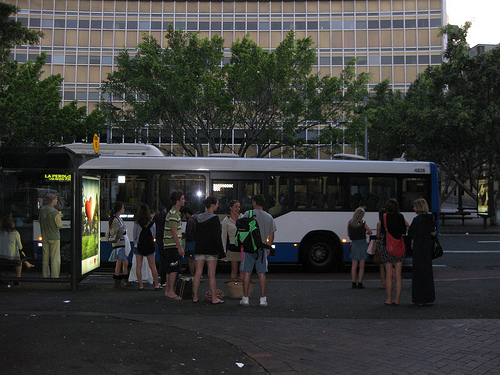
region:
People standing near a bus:
[7, 188, 442, 315]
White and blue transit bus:
[80, 152, 442, 269]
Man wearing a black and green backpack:
[235, 190, 279, 308]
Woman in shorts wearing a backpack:
[127, 199, 162, 291]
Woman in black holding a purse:
[410, 193, 442, 308]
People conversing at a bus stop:
[157, 185, 277, 311]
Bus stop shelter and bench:
[0, 141, 103, 292]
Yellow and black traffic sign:
[87, 131, 101, 154]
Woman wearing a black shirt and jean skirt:
[345, 204, 372, 294]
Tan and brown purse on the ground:
[222, 263, 258, 303]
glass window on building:
[16, 17, 28, 27]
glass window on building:
[53, 18, 64, 29]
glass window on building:
[100, 21, 114, 29]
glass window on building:
[151, 20, 162, 30]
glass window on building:
[198, 20, 210, 32]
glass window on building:
[235, 19, 246, 32]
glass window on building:
[282, 21, 292, 31]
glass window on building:
[307, 19, 319, 29]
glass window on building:
[330, 19, 342, 30]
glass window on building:
[342, 17, 355, 29]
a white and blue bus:
[78, 151, 441, 273]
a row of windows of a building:
[27, 6, 442, 31]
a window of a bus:
[285, 173, 321, 215]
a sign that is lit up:
[75, 170, 102, 288]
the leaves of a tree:
[437, 82, 492, 137]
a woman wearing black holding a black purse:
[405, 195, 445, 307]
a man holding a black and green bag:
[233, 193, 278, 306]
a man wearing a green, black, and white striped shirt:
[160, 188, 187, 303]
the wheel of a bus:
[298, 230, 344, 275]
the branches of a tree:
[175, 117, 287, 155]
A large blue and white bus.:
[46, 137, 464, 290]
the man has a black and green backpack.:
[234, 211, 263, 258]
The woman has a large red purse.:
[379, 211, 404, 262]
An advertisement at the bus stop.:
[73, 167, 107, 297]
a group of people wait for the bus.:
[156, 184, 284, 318]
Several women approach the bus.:
[344, 198, 448, 321]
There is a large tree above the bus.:
[96, 5, 393, 163]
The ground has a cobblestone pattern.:
[318, 304, 449, 371]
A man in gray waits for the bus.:
[40, 188, 65, 280]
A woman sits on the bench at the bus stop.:
[1, 208, 32, 278]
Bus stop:
[11, 141, 103, 287]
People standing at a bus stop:
[21, 141, 445, 305]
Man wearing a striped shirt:
[160, 191, 190, 246]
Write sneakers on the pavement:
[231, 285, 274, 312]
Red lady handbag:
[374, 209, 411, 274]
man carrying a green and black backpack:
[230, 193, 278, 258]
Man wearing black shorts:
[155, 243, 185, 278]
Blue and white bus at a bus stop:
[80, 150, 442, 277]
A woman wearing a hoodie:
[187, 195, 227, 262]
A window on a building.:
[343, 54, 355, 69]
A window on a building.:
[368, 53, 382, 64]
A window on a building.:
[381, 52, 390, 62]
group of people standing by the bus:
[0, 189, 444, 309]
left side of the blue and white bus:
[77, 155, 440, 273]